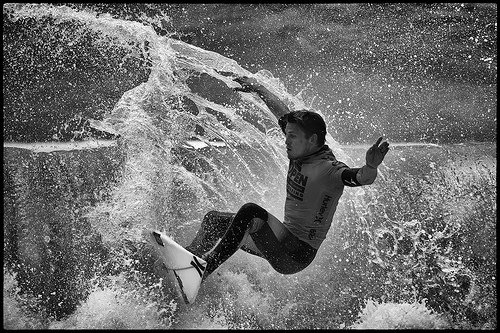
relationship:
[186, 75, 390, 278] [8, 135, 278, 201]
man riding waves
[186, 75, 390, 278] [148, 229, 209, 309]
man on board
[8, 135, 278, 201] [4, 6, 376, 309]
waves are in ocean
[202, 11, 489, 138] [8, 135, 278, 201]
sky above waves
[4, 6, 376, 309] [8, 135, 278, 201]
water above waves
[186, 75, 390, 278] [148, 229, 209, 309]
man riding board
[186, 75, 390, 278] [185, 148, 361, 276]
man wearing wetsuit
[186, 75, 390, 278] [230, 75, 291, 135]
man has arm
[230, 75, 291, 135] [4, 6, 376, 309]
arm touches water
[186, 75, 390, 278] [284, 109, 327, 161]
man has head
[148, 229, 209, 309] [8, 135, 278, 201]
board cuts through waves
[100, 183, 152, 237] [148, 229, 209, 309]
splash comes from board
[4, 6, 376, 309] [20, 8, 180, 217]
water makes wall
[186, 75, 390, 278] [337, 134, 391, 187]
man has arm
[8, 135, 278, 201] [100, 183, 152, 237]
waves make splash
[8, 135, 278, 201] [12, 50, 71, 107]
waves make spray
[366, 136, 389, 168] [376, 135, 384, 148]
hand has finger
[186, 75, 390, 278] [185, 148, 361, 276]
man wears wetsuit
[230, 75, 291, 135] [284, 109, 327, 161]
arm over head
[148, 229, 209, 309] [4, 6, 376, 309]
board in water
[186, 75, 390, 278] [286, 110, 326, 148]
man has hair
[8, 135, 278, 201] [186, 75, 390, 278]
waves crash over man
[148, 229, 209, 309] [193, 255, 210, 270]
board has stripe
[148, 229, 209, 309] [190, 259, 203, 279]
board has stripe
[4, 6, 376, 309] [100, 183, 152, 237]
water makes splash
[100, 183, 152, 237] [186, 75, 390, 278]
splash around man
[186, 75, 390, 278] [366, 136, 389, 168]
man has hand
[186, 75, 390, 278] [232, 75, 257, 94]
man has hand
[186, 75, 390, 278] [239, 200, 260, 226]
man has knee